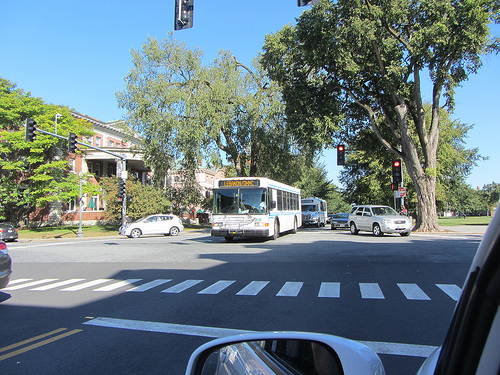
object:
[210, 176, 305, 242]
bus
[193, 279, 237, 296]
line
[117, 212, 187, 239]
car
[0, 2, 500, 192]
sky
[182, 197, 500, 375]
car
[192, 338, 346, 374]
mirror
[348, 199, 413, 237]
suv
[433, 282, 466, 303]
lines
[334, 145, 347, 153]
traffic light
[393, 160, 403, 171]
traffic light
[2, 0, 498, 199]
no clouds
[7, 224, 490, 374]
road